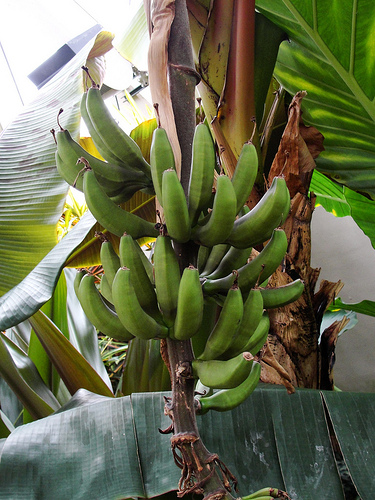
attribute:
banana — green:
[69, 162, 156, 238]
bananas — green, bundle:
[70, 232, 209, 345]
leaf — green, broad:
[256, 2, 372, 246]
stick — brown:
[148, 2, 255, 393]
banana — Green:
[227, 176, 288, 247]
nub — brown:
[163, 169, 172, 174]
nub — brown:
[116, 229, 132, 240]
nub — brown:
[184, 266, 199, 273]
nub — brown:
[270, 170, 283, 183]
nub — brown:
[272, 225, 287, 237]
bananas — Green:
[82, 88, 152, 171]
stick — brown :
[157, 3, 201, 424]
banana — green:
[24, 72, 325, 417]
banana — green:
[197, 172, 237, 249]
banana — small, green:
[216, 180, 267, 234]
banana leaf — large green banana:
[283, 35, 361, 182]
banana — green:
[149, 90, 243, 245]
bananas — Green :
[56, 86, 300, 405]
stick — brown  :
[169, 343, 231, 497]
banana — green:
[57, 127, 150, 188]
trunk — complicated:
[143, 0, 341, 389]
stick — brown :
[218, 4, 258, 152]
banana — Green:
[88, 86, 145, 177]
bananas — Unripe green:
[150, 131, 188, 241]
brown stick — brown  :
[158, 1, 240, 498]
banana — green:
[153, 168, 192, 252]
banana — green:
[187, 123, 217, 218]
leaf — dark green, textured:
[341, 184, 372, 248]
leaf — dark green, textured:
[324, 297, 373, 319]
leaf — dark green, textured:
[314, 306, 356, 342]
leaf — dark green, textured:
[1, 188, 154, 329]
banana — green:
[146, 154, 206, 249]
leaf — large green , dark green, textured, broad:
[250, 1, 373, 193]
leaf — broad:
[3, 26, 123, 284]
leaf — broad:
[4, 189, 139, 339]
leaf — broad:
[17, 311, 111, 391]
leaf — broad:
[1, 332, 61, 423]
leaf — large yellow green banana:
[3, 29, 115, 307]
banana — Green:
[161, 167, 189, 239]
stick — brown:
[142, 0, 238, 498]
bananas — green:
[13, 83, 312, 252]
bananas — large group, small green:
[197, 179, 233, 244]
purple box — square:
[12, 23, 126, 106]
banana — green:
[81, 65, 152, 179]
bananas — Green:
[66, 69, 290, 410]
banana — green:
[79, 236, 208, 345]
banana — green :
[193, 354, 250, 384]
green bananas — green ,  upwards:
[19, 83, 338, 397]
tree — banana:
[69, 4, 346, 407]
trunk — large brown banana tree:
[0, 354, 373, 497]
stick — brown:
[166, 374, 211, 466]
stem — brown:
[167, 342, 202, 464]